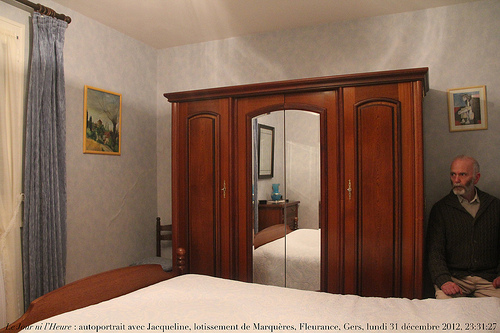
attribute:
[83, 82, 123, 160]
frame — of picture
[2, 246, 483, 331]
bedstead — wooden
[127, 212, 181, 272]
chair — ladder back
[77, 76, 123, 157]
painting — framed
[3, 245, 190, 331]
foot board — brown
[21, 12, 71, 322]
curtain — gray, blue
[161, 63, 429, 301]
wardrobe —  wood, brown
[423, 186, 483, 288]
sweater — black, brown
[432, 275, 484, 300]
pants — tan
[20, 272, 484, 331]
bedspread — white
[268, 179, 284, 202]
vase — blue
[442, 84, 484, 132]
picture — framed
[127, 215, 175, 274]
chair — wood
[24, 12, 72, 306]
curtains — blue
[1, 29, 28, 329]
curtains — white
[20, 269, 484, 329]
cover — white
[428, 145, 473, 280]
man — sitting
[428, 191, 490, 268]
sweater — black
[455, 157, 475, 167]
hair line — receding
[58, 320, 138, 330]
letter — black, print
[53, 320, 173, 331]
letter — print, black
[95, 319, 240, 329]
letter — black, print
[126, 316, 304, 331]
letter — print, black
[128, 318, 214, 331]
letter — black, print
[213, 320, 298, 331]
letter — black, print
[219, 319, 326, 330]
letter — print, black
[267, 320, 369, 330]
letter — black, print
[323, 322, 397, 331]
letter — print, black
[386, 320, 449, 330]
letter — black, print